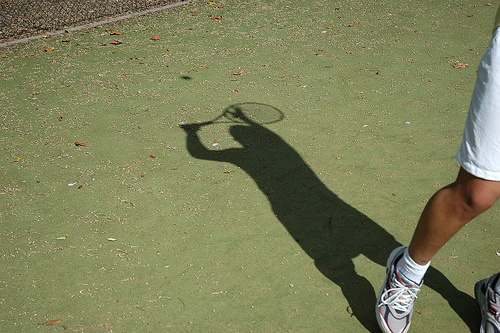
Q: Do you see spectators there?
A: No, there are no spectators.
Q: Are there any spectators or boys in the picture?
A: No, there are no spectators or boys.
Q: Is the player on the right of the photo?
A: Yes, the player is on the right of the image.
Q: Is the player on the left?
A: No, the player is on the right of the image.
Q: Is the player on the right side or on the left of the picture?
A: The player is on the right of the image.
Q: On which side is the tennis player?
A: The player is on the right of the image.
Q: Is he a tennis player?
A: Yes, this is a tennis player.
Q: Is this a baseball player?
A: No, this is a tennis player.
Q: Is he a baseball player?
A: No, this is a tennis player.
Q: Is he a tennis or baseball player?
A: This is a tennis player.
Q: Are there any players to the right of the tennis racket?
A: Yes, there is a player to the right of the tennis racket.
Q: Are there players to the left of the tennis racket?
A: No, the player is to the right of the tennis racket.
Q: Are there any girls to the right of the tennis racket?
A: No, there is a player to the right of the tennis racket.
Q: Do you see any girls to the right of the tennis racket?
A: No, there is a player to the right of the tennis racket.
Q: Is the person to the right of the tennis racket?
A: Yes, the player is to the right of the tennis racket.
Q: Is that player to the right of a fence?
A: No, the player is to the right of the tennis racket.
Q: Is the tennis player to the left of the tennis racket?
A: No, the player is to the right of the tennis racket.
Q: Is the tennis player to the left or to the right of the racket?
A: The player is to the right of the racket.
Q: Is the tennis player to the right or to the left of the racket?
A: The player is to the right of the racket.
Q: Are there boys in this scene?
A: No, there are no boys.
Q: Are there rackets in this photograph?
A: Yes, there is a racket.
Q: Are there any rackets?
A: Yes, there is a racket.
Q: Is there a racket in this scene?
A: Yes, there is a racket.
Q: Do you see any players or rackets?
A: Yes, there is a racket.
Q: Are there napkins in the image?
A: No, there are no napkins.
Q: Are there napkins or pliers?
A: No, there are no napkins or pliers.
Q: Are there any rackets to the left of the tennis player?
A: Yes, there is a racket to the left of the player.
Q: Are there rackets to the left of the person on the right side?
A: Yes, there is a racket to the left of the player.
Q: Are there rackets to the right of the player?
A: No, the racket is to the left of the player.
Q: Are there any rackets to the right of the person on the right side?
A: No, the racket is to the left of the player.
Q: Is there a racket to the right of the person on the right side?
A: No, the racket is to the left of the player.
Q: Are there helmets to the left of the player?
A: No, there is a racket to the left of the player.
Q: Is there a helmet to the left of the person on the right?
A: No, there is a racket to the left of the player.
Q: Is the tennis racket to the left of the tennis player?
A: Yes, the tennis racket is to the left of the player.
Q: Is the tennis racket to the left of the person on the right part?
A: Yes, the tennis racket is to the left of the player.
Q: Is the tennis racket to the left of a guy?
A: No, the tennis racket is to the left of the player.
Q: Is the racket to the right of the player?
A: No, the racket is to the left of the player.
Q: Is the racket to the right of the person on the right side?
A: No, the racket is to the left of the player.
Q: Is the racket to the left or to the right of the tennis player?
A: The racket is to the left of the player.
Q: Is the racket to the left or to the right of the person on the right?
A: The racket is to the left of the player.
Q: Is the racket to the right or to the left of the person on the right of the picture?
A: The racket is to the left of the player.